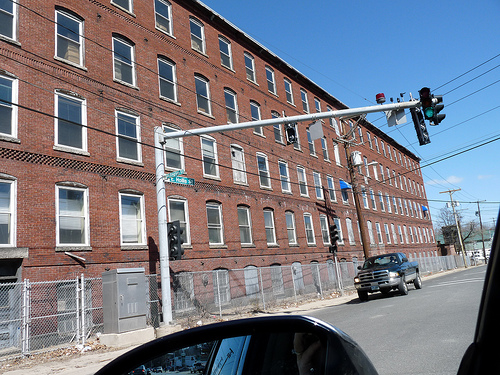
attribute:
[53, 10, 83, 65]
window — rectangular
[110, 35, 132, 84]
window — rectangular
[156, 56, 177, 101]
window — rectangular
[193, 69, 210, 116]
window — rectangular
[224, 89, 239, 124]
window — rectangular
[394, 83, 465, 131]
light — traffic, black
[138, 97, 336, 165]
pole — gray, metal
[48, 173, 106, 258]
window — rectangular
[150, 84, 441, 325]
poles — utility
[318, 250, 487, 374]
street — city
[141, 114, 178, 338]
metal pole — gray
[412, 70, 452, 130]
light — traffic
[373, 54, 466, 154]
light — green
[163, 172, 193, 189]
street sign — green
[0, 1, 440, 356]
building — brown, fenced, brick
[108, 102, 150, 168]
window — rectangular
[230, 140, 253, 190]
window — rectangular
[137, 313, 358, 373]
view mirror — black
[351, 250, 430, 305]
truck — black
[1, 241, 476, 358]
fence — chain link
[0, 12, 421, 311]
building — long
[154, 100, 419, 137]
bar — cross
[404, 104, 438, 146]
lights — traffic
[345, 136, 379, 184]
transformer — white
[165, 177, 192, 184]
sign — blue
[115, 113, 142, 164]
window — rectangular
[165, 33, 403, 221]
building — tall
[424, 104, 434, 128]
lights — on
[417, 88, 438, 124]
light — green 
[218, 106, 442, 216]
window — red